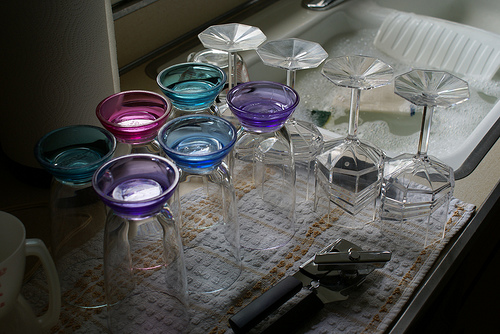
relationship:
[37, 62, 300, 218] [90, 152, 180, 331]
base of glass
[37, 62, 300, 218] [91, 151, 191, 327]
base of drinking glass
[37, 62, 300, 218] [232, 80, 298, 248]
base of drinking glass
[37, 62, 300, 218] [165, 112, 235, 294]
base of drinking glass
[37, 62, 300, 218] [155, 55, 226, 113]
base of glass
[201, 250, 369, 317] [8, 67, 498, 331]
can opener on counter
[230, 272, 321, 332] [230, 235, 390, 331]
handle of can opener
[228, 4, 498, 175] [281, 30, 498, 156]
sink with water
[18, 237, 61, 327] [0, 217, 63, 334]
handle attached to coffee mug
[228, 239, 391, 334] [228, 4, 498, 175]
can opener laying next to sink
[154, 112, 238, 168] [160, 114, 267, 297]
base holding glass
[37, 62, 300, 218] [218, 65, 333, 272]
base holding glass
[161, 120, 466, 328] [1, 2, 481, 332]
towel lying on counter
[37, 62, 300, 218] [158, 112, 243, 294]
base holding glass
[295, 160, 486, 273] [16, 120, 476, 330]
stemware sitting on towel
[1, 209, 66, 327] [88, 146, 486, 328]
measuring cup sitting on towel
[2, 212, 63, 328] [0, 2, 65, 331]
coffee mug sitting in corner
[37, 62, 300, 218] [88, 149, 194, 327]
base holding glass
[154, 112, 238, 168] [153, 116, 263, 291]
base holding glass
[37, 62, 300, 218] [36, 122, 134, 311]
base holding glass